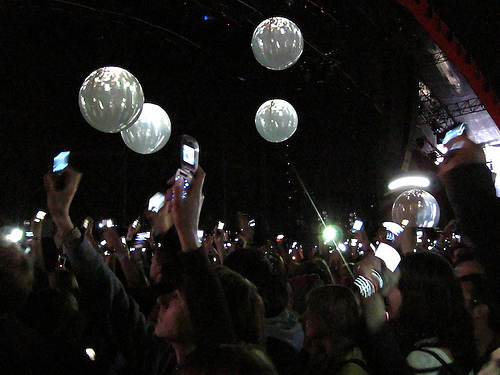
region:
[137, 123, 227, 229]
the phone is silver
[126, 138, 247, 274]
the phone is silver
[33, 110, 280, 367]
people's arms are up in the air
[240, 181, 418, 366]
people's arms are up in the air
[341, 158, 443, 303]
people's arms are up in the air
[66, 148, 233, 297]
people's arms are up in the air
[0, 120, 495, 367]
several people holding up their cellphones in the air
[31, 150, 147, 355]
the arm of a person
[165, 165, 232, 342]
the arm of a person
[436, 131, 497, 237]
the arm of a person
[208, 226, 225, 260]
the hand of a person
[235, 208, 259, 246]
the hand of a person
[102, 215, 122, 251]
the hand of a person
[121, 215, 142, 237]
the hand of a person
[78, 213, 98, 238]
the hand of a person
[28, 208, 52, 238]
the hand of a person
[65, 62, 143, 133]
floating paper lamp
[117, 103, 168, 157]
floating paper lamp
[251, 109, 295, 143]
floating paper lamp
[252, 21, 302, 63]
a floating paper lamp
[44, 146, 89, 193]
a cellular phone with a lit screen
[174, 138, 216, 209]
a cellular phone with a lit screen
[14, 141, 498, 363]
a crowd of people gathered together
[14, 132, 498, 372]
people at a concert event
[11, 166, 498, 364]
crowd of people in an arena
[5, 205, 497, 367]
crowd of people in a warehouse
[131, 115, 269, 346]
people are holding their phones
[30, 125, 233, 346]
people are holding their phones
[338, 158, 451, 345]
people are holding their phones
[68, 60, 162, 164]
the silver balls of light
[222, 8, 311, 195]
the silver balls of light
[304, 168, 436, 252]
the silver balls of light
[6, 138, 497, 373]
several people at an event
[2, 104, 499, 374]
several people holding up their cellphone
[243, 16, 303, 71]
a shiny silver ball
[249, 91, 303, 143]
a shiny silver ball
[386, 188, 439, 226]
a shiny silver ball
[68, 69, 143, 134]
a shiny silver ball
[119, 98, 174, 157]
a shiny silver ball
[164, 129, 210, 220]
a cellphone held in a hand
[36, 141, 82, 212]
a cellphone held in a hand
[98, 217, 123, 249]
a cellphone held in a hand